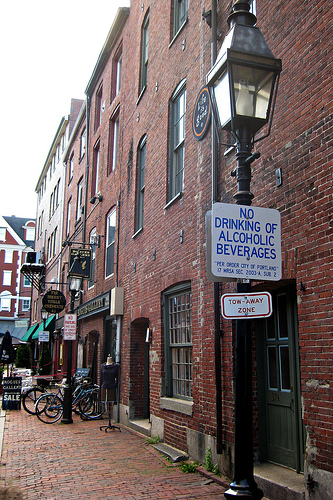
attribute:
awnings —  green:
[31, 313, 56, 339]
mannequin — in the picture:
[98, 350, 124, 431]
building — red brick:
[84, 2, 319, 494]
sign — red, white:
[210, 288, 278, 322]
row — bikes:
[20, 373, 105, 423]